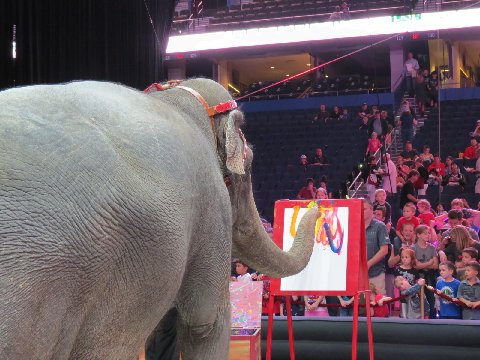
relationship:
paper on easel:
[284, 211, 348, 275] [271, 195, 370, 296]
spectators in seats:
[368, 158, 480, 284] [279, 160, 324, 183]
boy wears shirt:
[413, 256, 466, 320] [369, 137, 388, 158]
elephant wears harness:
[160, 76, 318, 300] [206, 78, 283, 129]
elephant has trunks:
[160, 76, 318, 300] [248, 209, 330, 281]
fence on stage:
[261, 315, 473, 360] [237, 345, 378, 360]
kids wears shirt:
[389, 195, 452, 277] [369, 137, 388, 158]